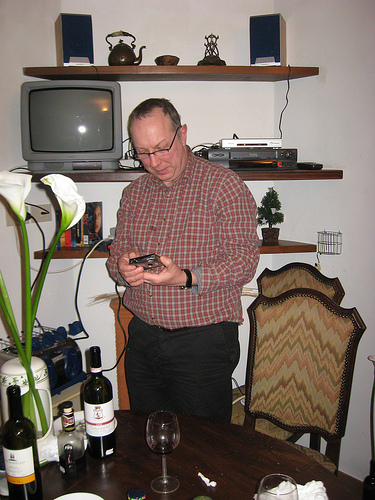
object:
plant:
[31, 174, 87, 327]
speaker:
[248, 13, 286, 66]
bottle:
[57, 401, 85, 493]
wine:
[83, 347, 116, 461]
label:
[84, 398, 115, 437]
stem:
[23, 254, 32, 358]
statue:
[197, 33, 226, 65]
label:
[2, 444, 36, 487]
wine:
[145, 409, 180, 492]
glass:
[256, 474, 300, 499]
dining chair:
[243, 288, 367, 468]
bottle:
[83, 345, 116, 458]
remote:
[297, 162, 323, 170]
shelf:
[32, 171, 344, 181]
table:
[0, 408, 374, 499]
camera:
[128, 253, 162, 270]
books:
[84, 202, 103, 246]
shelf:
[33, 245, 317, 259]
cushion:
[247, 293, 354, 435]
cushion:
[259, 266, 335, 301]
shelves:
[23, 65, 320, 81]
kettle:
[106, 31, 147, 67]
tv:
[20, 80, 121, 172]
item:
[258, 187, 284, 242]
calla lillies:
[0, 169, 37, 362]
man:
[105, 97, 260, 419]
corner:
[264, 0, 284, 135]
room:
[0, 2, 369, 497]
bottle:
[2, 385, 39, 497]